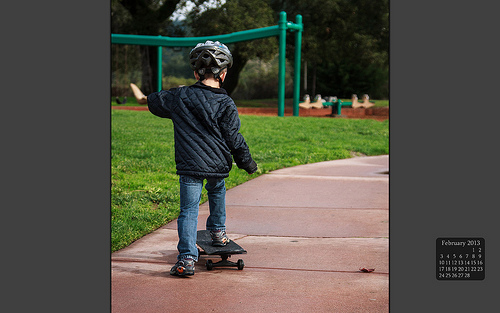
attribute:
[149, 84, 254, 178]
coat — black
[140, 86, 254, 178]
jacket — dark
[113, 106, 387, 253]
grass — green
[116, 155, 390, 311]
sidewalk — tan, wet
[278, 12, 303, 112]
poles — green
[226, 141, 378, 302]
ground — concrete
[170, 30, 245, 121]
child — black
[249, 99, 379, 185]
gras — short, green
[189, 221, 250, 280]
skateboard — black, long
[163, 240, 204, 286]
tennis shoe — gray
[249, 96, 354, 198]
grass — green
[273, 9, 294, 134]
pole — tall, green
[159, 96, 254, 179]
jacket — black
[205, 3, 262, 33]
tree leaves — green